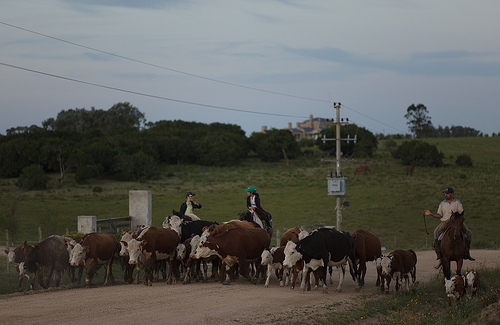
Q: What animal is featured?
A: Cows.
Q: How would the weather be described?
A: Partly cloudy.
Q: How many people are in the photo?
A: Three.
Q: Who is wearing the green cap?
A: The person in the middle.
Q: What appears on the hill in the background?
A: A house.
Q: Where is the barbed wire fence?
A: Along the lefthand side of the road.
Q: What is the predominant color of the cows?
A: Brown.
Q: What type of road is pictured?
A: Dirt road.